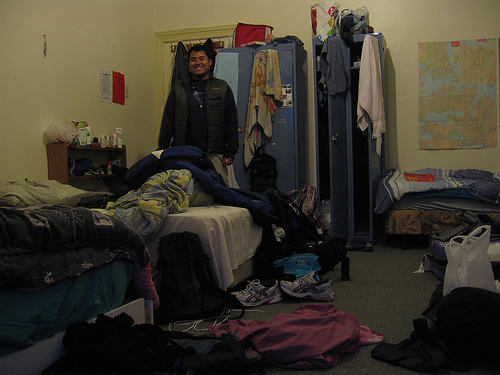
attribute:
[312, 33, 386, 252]
locker — blue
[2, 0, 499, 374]
room — messy,  slightly messy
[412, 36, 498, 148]
map — Large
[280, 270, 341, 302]
shoe — running shoe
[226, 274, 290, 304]
shoe — running shoe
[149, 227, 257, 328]
back pack — black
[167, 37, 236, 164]
man — smiling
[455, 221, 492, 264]
plastic bag —  plastic,  white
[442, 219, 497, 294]
plastic bag —  white,  plastic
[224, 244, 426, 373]
floor — cluttered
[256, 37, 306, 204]
locker —  twin,  blue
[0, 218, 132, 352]
blanket — blue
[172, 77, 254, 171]
vest — green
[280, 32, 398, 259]
lockers —  opened,  blue,  twin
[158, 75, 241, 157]
jacket — black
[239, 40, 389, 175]
towels —  several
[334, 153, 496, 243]
bed — unmade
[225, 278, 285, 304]
shoe — tennis shoe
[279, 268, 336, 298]
shoe — tennis shoe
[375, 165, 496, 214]
comforter — blue and white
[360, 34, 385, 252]
door — locker door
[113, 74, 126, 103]
paper — red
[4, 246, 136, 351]
sofa top — blue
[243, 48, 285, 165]
clothing — A piece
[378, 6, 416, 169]
wall —  room's